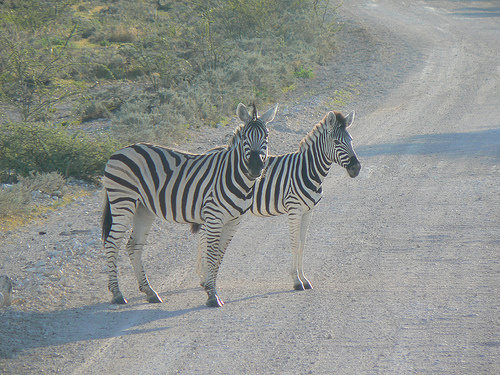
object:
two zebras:
[96, 103, 362, 308]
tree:
[0, 21, 116, 120]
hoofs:
[203, 290, 223, 309]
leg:
[282, 209, 303, 276]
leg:
[296, 210, 310, 278]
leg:
[200, 217, 223, 291]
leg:
[123, 218, 154, 292]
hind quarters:
[101, 146, 135, 199]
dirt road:
[0, 0, 499, 374]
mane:
[295, 110, 337, 158]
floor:
[0, 0, 499, 374]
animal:
[96, 101, 283, 309]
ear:
[233, 101, 251, 122]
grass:
[0, 0, 348, 235]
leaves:
[22, 126, 37, 136]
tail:
[96, 176, 113, 248]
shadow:
[351, 125, 499, 172]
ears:
[258, 100, 283, 124]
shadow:
[0, 284, 294, 360]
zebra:
[187, 106, 362, 292]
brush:
[0, 1, 349, 234]